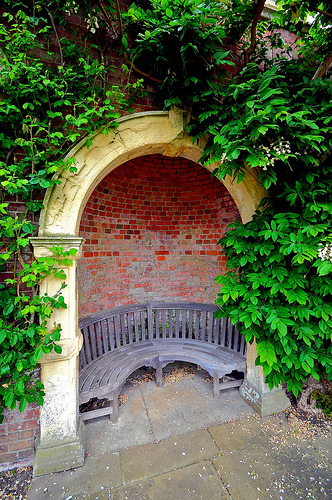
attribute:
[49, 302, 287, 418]
bench — semi circled, gray, wooden, circular, unique, unkept, curved, grey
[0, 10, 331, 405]
leaves — green, leafy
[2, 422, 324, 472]
petals — concrete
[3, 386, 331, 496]
walkway — brown, stone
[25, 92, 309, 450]
shelter — brick, yellow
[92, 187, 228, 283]
bricks — red, made of stone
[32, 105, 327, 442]
archway — old, discolored, pictured, here, tann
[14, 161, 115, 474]
pillar — white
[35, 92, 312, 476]
stones — discolored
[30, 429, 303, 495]
these — bricks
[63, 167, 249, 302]
wall — brick, red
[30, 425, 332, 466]
slabs — on the ground